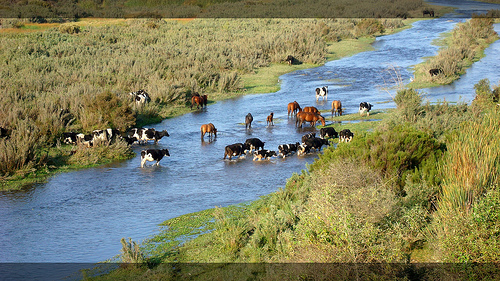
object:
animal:
[358, 101, 374, 117]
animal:
[244, 112, 253, 129]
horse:
[301, 106, 321, 115]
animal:
[223, 142, 248, 161]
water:
[0, 1, 499, 278]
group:
[222, 126, 356, 162]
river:
[0, 0, 500, 279]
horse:
[199, 122, 218, 144]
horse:
[266, 112, 273, 126]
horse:
[297, 111, 326, 128]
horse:
[331, 100, 343, 118]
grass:
[65, 106, 500, 281]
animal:
[139, 148, 171, 169]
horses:
[286, 100, 302, 119]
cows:
[252, 149, 278, 162]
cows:
[303, 137, 330, 153]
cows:
[277, 141, 302, 160]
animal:
[199, 122, 218, 142]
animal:
[190, 93, 209, 110]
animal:
[314, 85, 329, 102]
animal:
[266, 111, 275, 126]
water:
[40, 177, 150, 236]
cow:
[242, 137, 266, 151]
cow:
[337, 128, 354, 144]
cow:
[319, 126, 340, 140]